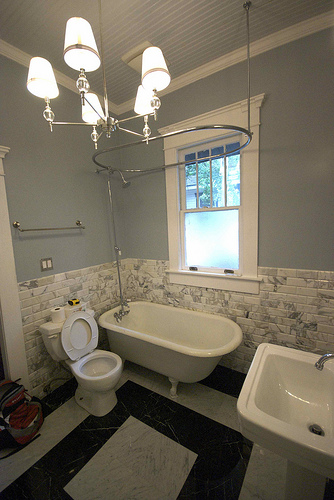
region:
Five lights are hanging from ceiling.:
[29, 34, 186, 150]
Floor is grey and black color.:
[55, 402, 189, 483]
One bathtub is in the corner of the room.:
[114, 296, 232, 377]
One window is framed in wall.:
[159, 122, 277, 287]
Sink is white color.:
[246, 341, 331, 442]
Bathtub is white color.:
[88, 289, 254, 374]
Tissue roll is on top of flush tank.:
[42, 296, 82, 335]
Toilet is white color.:
[40, 317, 119, 409]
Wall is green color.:
[12, 150, 110, 223]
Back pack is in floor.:
[1, 380, 53, 449]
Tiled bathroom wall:
[2, 276, 130, 327]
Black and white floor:
[57, 419, 264, 493]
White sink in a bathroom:
[247, 333, 322, 489]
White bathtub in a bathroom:
[93, 288, 260, 394]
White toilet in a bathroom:
[31, 318, 138, 427]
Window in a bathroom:
[157, 148, 261, 286]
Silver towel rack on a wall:
[7, 210, 114, 247]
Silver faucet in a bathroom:
[95, 163, 141, 338]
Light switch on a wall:
[34, 253, 62, 273]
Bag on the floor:
[1, 371, 55, 459]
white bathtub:
[92, 255, 232, 385]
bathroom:
[9, 198, 324, 488]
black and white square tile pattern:
[5, 338, 304, 495]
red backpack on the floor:
[0, 373, 61, 452]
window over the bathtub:
[97, 152, 265, 375]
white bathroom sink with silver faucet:
[246, 327, 330, 441]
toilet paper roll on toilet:
[45, 280, 108, 417]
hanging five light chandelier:
[29, 21, 179, 143]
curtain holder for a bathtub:
[83, 64, 265, 183]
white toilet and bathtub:
[56, 286, 254, 414]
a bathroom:
[6, 41, 327, 495]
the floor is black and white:
[25, 372, 326, 497]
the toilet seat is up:
[49, 300, 139, 412]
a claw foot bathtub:
[103, 288, 241, 399]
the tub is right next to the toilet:
[43, 291, 250, 417]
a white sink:
[244, 333, 331, 463]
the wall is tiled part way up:
[30, 257, 332, 404]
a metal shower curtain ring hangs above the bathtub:
[89, 124, 255, 306]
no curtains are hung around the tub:
[81, 127, 267, 353]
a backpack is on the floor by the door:
[2, 375, 54, 459]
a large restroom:
[3, 3, 309, 488]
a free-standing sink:
[232, 327, 323, 494]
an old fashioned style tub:
[97, 292, 236, 396]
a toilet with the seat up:
[59, 307, 119, 413]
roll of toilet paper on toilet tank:
[33, 299, 74, 341]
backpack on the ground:
[0, 372, 51, 451]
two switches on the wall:
[32, 250, 60, 275]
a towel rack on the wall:
[7, 202, 94, 246]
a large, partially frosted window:
[162, 108, 258, 289]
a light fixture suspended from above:
[18, 1, 181, 155]